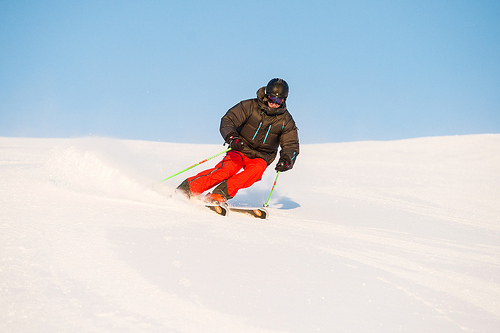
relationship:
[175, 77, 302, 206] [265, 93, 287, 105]
man has goggles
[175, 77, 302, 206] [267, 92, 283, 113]
man has a face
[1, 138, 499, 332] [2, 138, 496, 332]
snow on ground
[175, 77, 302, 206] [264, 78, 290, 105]
man has helmet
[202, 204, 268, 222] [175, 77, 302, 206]
skis on man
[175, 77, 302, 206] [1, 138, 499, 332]
man on snow